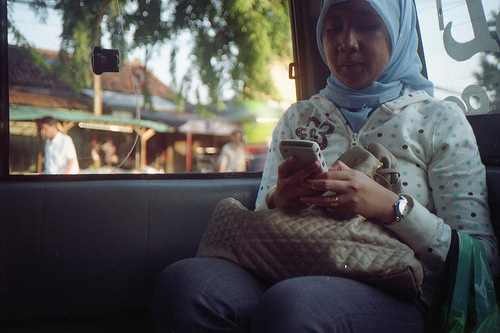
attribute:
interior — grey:
[7, 177, 268, 331]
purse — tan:
[197, 195, 427, 288]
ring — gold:
[333, 192, 341, 211]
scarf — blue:
[376, 2, 428, 127]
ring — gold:
[325, 191, 342, 208]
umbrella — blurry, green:
[218, 92, 290, 141]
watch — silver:
[384, 190, 415, 226]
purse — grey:
[174, 170, 436, 255]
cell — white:
[274, 132, 325, 171]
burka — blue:
[310, 0, 434, 131]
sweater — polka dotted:
[252, 89, 496, 267]